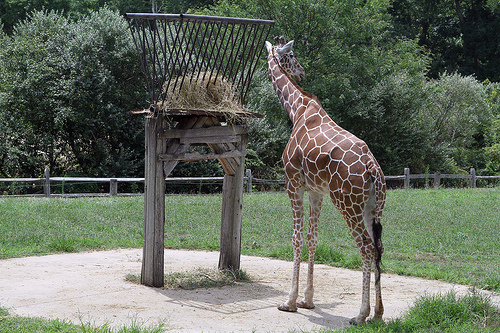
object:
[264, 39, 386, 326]
giraffe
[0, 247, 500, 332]
concrete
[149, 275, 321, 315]
shadow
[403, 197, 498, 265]
grass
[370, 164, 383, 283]
tail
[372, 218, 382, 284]
hair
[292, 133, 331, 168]
spots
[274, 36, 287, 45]
horns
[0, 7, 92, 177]
trees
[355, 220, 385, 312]
legs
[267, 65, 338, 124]
neck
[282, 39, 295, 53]
ears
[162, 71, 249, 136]
hay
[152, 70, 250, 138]
manger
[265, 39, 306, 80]
head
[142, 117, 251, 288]
stand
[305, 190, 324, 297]
front legs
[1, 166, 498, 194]
fence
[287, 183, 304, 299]
left front leg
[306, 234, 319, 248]
knee